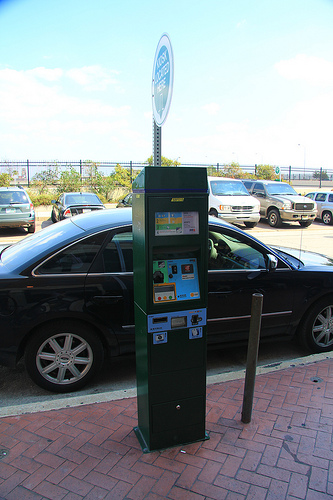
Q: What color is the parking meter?
A: Green.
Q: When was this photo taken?
A: In the daytime.